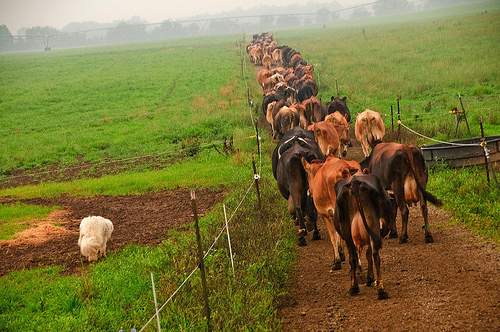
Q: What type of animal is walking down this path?
A: Cows.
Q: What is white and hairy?
A: Dog.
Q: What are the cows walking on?
A: Dirt path.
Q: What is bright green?
A: Grass.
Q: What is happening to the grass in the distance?
A: It's being watered.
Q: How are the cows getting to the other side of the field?
A: Walking in the path.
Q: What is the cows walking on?
A: A dirt road in the field.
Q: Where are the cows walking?
A: A pasture.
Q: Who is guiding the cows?
A: Cattle rancher.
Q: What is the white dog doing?
A: Sniffing the ground.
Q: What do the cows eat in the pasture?
A: Green grass.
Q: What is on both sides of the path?
A: Fences.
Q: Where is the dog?
A: Standing on the ground in a pasture.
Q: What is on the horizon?
A: Trees.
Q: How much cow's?
A: Heard's.